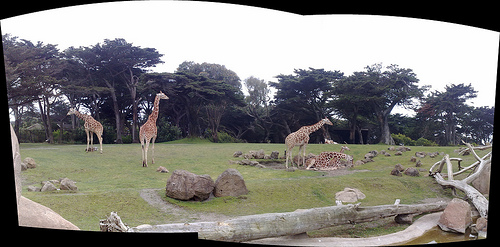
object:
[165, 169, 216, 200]
rock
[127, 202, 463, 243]
trunk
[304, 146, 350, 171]
giraffe laying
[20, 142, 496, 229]
green field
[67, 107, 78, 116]
head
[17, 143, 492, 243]
field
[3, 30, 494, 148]
trees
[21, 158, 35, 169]
rock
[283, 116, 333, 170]
giraffe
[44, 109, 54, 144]
trunk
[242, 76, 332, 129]
wall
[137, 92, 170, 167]
giraffe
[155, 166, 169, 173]
rock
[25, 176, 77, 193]
rocks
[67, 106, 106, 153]
giraffe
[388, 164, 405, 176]
rock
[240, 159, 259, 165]
rock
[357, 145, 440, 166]
rocks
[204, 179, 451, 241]
log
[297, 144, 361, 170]
giraffe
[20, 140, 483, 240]
grass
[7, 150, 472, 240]
ground